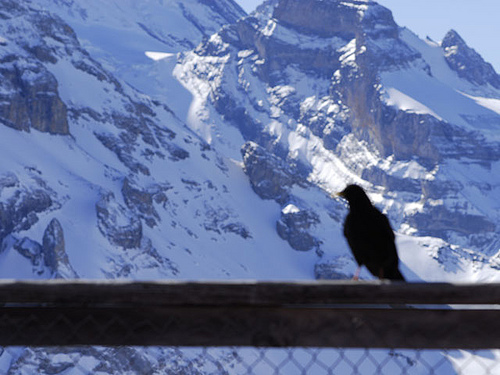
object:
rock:
[323, 77, 404, 120]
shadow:
[110, 73, 210, 173]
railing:
[0, 278, 484, 351]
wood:
[1, 278, 497, 308]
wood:
[1, 304, 499, 349]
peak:
[191, 1, 420, 88]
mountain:
[1, 2, 500, 375]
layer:
[204, 18, 420, 213]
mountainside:
[2, 2, 499, 373]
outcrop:
[2, 165, 51, 243]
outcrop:
[40, 215, 78, 277]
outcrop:
[89, 185, 144, 247]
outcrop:
[1, 38, 71, 136]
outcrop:
[91, 189, 148, 249]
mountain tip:
[187, 1, 434, 86]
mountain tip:
[438, 27, 475, 64]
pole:
[1, 276, 500, 349]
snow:
[1, 1, 500, 374]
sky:
[233, 1, 500, 76]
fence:
[0, 282, 499, 375]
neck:
[340, 195, 371, 207]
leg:
[353, 265, 361, 276]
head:
[336, 182, 367, 199]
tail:
[384, 267, 405, 285]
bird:
[333, 183, 408, 283]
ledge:
[1, 274, 500, 375]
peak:
[435, 26, 462, 46]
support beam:
[0, 302, 500, 347]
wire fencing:
[0, 328, 499, 374]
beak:
[335, 192, 340, 196]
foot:
[349, 275, 361, 283]